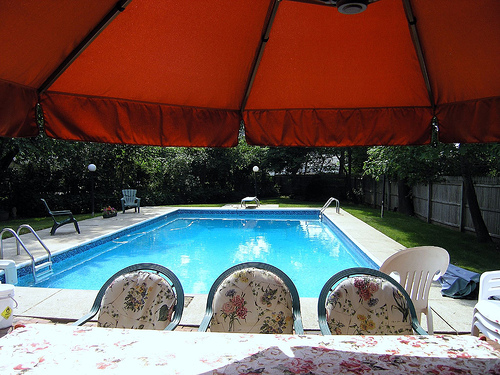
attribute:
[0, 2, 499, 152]
umbrella — large, red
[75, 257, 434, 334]
chairs — flowery, white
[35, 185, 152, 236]
chair — plastic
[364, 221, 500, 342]
chair — plastic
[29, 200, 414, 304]
pool — large, blue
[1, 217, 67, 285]
ladder — metal